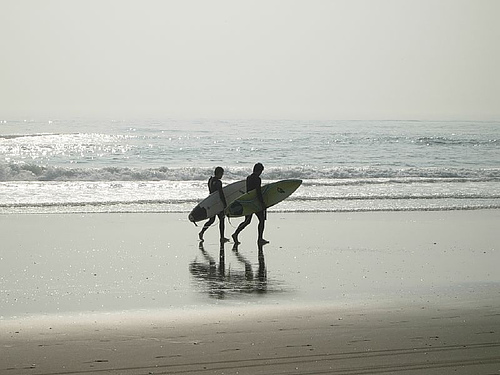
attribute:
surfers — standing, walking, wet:
[206, 156, 282, 248]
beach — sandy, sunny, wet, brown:
[327, 223, 421, 282]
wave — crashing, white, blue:
[98, 148, 136, 188]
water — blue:
[240, 143, 276, 167]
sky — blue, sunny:
[160, 11, 227, 47]